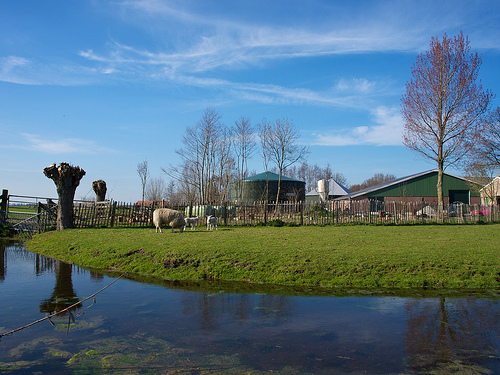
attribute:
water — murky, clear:
[1, 241, 500, 374]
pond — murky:
[0, 241, 498, 374]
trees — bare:
[133, 27, 499, 222]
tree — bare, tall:
[399, 27, 495, 222]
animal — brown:
[150, 205, 186, 232]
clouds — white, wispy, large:
[2, 2, 500, 156]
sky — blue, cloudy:
[0, 1, 499, 204]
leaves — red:
[404, 27, 497, 163]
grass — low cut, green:
[20, 223, 500, 297]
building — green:
[335, 167, 487, 218]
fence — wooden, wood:
[5, 194, 499, 229]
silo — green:
[238, 170, 307, 212]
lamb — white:
[183, 214, 202, 230]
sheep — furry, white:
[150, 207, 187, 229]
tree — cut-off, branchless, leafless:
[44, 163, 87, 228]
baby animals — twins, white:
[185, 210, 219, 230]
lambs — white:
[183, 212, 218, 232]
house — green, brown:
[336, 164, 485, 222]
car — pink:
[467, 204, 493, 222]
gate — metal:
[4, 194, 94, 233]